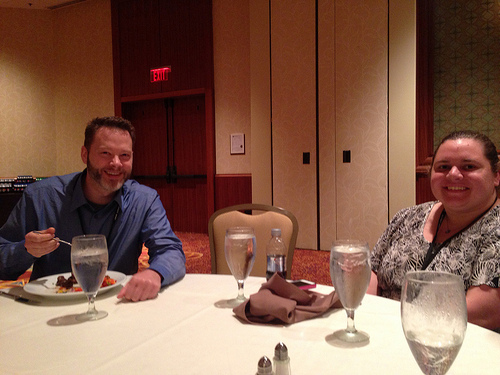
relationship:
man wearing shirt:
[1, 109, 199, 301] [1, 175, 187, 282]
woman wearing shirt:
[363, 131, 500, 324] [362, 200, 499, 306]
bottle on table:
[267, 229, 285, 280] [2, 270, 499, 375]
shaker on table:
[252, 340, 302, 372] [2, 270, 499, 375]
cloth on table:
[232, 272, 343, 326] [2, 270, 499, 375]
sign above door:
[150, 65, 171, 83] [119, 94, 209, 231]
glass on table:
[70, 229, 110, 321] [2, 270, 499, 375]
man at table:
[1, 109, 199, 301] [2, 270, 499, 375]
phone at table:
[289, 278, 315, 290] [2, 270, 499, 375]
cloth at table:
[232, 272, 343, 326] [2, 270, 499, 375]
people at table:
[2, 110, 497, 332] [2, 270, 499, 375]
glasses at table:
[69, 229, 474, 373] [2, 270, 499, 375]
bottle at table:
[267, 229, 285, 280] [2, 270, 499, 375]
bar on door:
[127, 172, 205, 184] [119, 94, 209, 231]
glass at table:
[70, 229, 110, 321] [2, 270, 499, 375]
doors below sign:
[119, 94, 209, 231] [150, 65, 171, 83]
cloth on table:
[232, 273, 353, 330] [2, 270, 499, 375]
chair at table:
[209, 203, 300, 276] [2, 270, 499, 375]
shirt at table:
[1, 175, 187, 282] [2, 270, 499, 375]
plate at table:
[20, 269, 124, 301] [2, 270, 499, 375]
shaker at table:
[252, 340, 302, 372] [2, 270, 499, 375]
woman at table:
[363, 131, 500, 324] [2, 270, 499, 375]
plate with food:
[20, 269, 124, 301] [54, 277, 81, 293]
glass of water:
[70, 229, 110, 321] [76, 254, 104, 295]